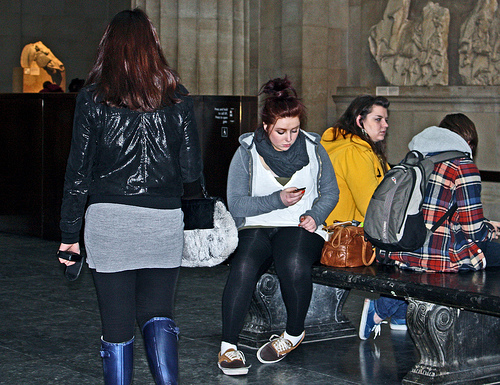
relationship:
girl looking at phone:
[217, 84, 343, 374] [291, 187, 305, 192]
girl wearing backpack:
[363, 111, 498, 281] [364, 153, 471, 250]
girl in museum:
[217, 84, 343, 374] [2, 1, 498, 385]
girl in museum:
[322, 91, 392, 227] [2, 1, 498, 385]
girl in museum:
[363, 111, 498, 281] [2, 1, 498, 385]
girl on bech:
[217, 84, 343, 374] [224, 254, 499, 384]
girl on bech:
[322, 91, 392, 227] [224, 254, 499, 384]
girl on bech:
[363, 111, 498, 281] [224, 254, 499, 384]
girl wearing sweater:
[322, 91, 392, 227] [323, 128, 390, 232]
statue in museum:
[21, 43, 67, 73] [2, 1, 498, 385]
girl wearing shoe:
[58, 6, 203, 378] [143, 317, 181, 384]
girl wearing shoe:
[58, 6, 203, 378] [99, 336, 135, 381]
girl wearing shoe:
[217, 84, 343, 374] [218, 350, 249, 378]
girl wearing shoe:
[217, 84, 343, 374] [256, 333, 301, 364]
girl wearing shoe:
[322, 91, 392, 227] [359, 295, 380, 343]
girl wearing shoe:
[322, 91, 392, 227] [392, 317, 408, 330]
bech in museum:
[224, 254, 499, 384] [2, 1, 498, 385]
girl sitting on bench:
[217, 84, 343, 374] [220, 224, 497, 382]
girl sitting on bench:
[322, 91, 392, 227] [220, 224, 497, 382]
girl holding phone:
[217, 84, 343, 374] [289, 189, 306, 197]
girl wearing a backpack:
[363, 111, 498, 281] [363, 149, 474, 251]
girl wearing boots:
[58, 6, 203, 378] [104, 314, 181, 383]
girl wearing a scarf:
[217, 84, 343, 374] [249, 133, 310, 171]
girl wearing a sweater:
[322, 91, 392, 227] [323, 128, 390, 232]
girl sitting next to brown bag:
[217, 84, 343, 374] [319, 212, 374, 269]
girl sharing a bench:
[363, 111, 498, 281] [228, 235, 498, 383]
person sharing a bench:
[311, 91, 402, 231] [228, 235, 498, 383]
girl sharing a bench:
[217, 84, 343, 374] [228, 235, 498, 383]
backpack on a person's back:
[372, 150, 442, 270] [360, 130, 485, 280]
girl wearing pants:
[58, 6, 203, 378] [200, 200, 342, 347]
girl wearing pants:
[217, 84, 343, 374] [200, 200, 342, 347]